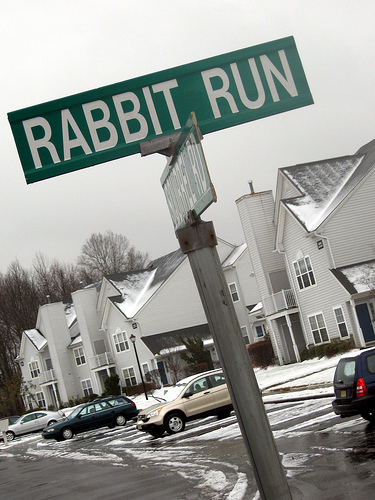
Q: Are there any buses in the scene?
A: No, there are no buses.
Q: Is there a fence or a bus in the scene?
A: No, there are no buses or fences.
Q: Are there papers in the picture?
A: No, there are no papers.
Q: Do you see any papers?
A: No, there are no papers.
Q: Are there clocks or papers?
A: No, there are no papers or clocks.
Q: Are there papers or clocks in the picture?
A: No, there are no papers or clocks.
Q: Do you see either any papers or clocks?
A: No, there are no papers or clocks.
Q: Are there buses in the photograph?
A: No, there are no buses.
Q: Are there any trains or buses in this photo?
A: No, there are no buses or trains.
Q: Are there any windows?
A: Yes, there is a window.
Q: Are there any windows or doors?
A: Yes, there is a window.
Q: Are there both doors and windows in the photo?
A: Yes, there are both a window and a door.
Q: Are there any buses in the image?
A: No, there are no buses.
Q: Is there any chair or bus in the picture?
A: No, there are no buses or chairs.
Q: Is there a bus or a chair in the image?
A: No, there are no buses or chairs.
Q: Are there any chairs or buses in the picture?
A: No, there are no buses or chairs.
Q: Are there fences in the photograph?
A: No, there are no fences.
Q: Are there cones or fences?
A: No, there are no fences or cones.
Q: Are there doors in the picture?
A: Yes, there is a door.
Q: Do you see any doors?
A: Yes, there is a door.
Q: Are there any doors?
A: Yes, there is a door.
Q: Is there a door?
A: Yes, there is a door.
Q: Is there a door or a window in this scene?
A: Yes, there is a door.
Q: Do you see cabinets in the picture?
A: No, there are no cabinets.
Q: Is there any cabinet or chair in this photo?
A: No, there are no cabinets or chairs.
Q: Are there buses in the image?
A: No, there are no buses.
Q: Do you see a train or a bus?
A: No, there are no buses or trains.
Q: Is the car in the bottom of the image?
A: Yes, the car is in the bottom of the image.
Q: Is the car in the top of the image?
A: No, the car is in the bottom of the image.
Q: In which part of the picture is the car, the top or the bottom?
A: The car is in the bottom of the image.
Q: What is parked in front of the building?
A: The car is parked in front of the building.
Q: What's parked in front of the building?
A: The car is parked in front of the building.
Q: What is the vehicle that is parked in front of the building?
A: The vehicle is a car.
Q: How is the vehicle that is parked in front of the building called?
A: The vehicle is a car.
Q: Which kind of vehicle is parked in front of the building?
A: The vehicle is a car.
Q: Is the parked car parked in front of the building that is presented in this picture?
A: Yes, the car is parked in front of the building.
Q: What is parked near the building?
A: The car is parked near the building.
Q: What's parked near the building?
A: The car is parked near the building.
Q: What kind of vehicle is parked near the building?
A: The vehicle is a car.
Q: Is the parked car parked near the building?
A: Yes, the car is parked near the building.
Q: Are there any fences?
A: No, there are no fences.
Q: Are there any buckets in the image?
A: No, there are no buckets.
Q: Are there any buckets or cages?
A: No, there are no buckets or cages.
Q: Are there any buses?
A: No, there are no buses.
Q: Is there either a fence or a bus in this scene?
A: No, there are no buses or fences.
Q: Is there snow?
A: Yes, there is snow.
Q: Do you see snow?
A: Yes, there is snow.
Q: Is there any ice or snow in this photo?
A: Yes, there is snow.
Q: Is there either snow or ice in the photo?
A: Yes, there is snow.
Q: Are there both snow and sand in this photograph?
A: No, there is snow but no sand.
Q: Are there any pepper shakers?
A: No, there are no pepper shakers.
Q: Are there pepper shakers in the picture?
A: No, there are no pepper shakers.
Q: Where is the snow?
A: The snow is on the ground.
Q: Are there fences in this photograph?
A: No, there are no fences.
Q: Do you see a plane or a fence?
A: No, there are no fences or airplanes.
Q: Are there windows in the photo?
A: Yes, there is a window.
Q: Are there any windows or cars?
A: Yes, there is a window.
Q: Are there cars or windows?
A: Yes, there is a window.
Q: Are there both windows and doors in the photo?
A: Yes, there are both a window and doors.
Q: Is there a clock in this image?
A: No, there are no clocks.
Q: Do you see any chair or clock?
A: No, there are no clocks or chairs.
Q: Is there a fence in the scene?
A: No, there are no fences.